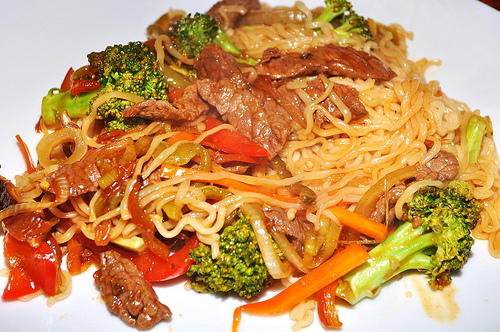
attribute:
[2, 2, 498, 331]
plate — white